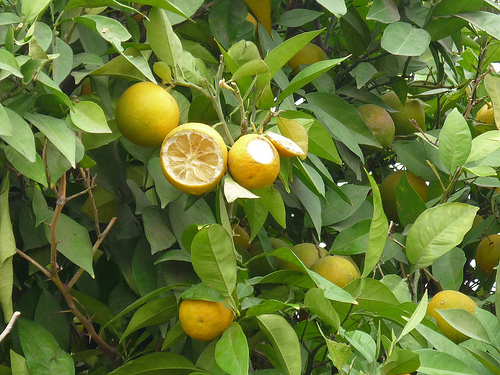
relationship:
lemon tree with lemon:
[0, 0, 499, 373] [160, 122, 230, 193]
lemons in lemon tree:
[104, 82, 493, 345] [0, 0, 499, 373]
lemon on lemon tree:
[310, 251, 359, 288] [0, 0, 499, 373]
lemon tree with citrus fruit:
[0, 0, 499, 373] [159, 122, 227, 195]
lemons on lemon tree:
[355, 102, 395, 150] [0, 0, 499, 373]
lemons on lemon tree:
[378, 169, 426, 227] [0, 0, 499, 373]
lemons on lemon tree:
[475, 234, 499, 277] [0, 0, 499, 373]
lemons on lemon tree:
[377, 90, 425, 141] [0, 0, 499, 373]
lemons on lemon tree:
[284, 42, 329, 74] [0, 0, 499, 373]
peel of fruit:
[274, 156, 279, 175] [227, 133, 279, 185]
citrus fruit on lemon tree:
[159, 122, 227, 195] [0, 0, 499, 373]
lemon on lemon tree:
[178, 297, 231, 335] [0, 0, 499, 373]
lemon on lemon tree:
[310, 256, 359, 281] [0, 0, 499, 373]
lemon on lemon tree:
[289, 42, 326, 69] [0, 0, 499, 373]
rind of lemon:
[251, 137, 278, 166] [216, 118, 291, 205]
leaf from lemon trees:
[68, 99, 111, 133] [2, 0, 499, 373]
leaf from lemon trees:
[22, 110, 75, 168] [2, 0, 499, 373]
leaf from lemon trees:
[1, 106, 36, 163] [2, 0, 499, 373]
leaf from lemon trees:
[41, 206, 96, 279] [2, 0, 499, 373]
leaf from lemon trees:
[31, 69, 73, 112] [2, 0, 499, 373]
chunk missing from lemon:
[163, 120, 237, 199] [160, 122, 230, 193]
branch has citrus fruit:
[32, 129, 121, 354] [159, 122, 227, 195]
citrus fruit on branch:
[159, 122, 227, 195] [32, 129, 121, 354]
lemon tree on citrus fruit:
[0, 0, 499, 373] [159, 123, 228, 195]